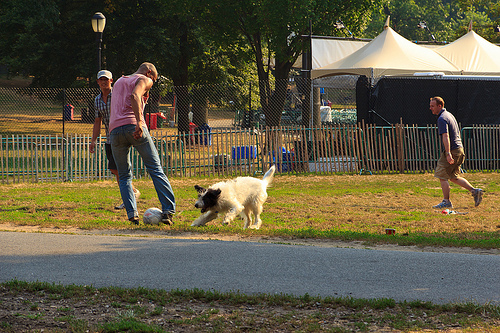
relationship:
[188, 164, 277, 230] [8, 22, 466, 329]
dog in park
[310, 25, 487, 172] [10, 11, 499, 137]
tent in background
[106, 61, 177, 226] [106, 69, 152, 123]
man kicking shirt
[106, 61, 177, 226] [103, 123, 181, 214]
man kicking jeans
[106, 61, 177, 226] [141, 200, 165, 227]
man kicking ball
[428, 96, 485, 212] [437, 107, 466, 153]
man wearing shirt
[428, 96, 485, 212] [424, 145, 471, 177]
man wearing shorts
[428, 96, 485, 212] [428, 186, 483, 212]
man wearing tennis shoes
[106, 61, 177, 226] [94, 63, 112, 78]
man wearing cap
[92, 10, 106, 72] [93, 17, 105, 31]
lamp with globe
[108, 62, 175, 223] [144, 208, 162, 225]
man playing ball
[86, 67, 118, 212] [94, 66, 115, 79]
man wearing a hat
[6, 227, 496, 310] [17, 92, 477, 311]
path in park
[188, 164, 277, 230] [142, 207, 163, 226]
dog playing ball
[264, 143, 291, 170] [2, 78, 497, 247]
object on ground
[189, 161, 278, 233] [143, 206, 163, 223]
dog trying to get a ball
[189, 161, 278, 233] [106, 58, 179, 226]
dog by man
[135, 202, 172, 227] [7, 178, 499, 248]
ball on ground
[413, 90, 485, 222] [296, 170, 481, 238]
man on grass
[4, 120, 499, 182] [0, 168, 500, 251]
fencing around grass